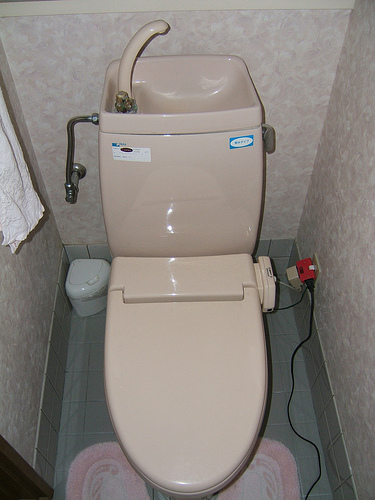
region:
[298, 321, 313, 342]
the chords is black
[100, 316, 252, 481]
the toilet seat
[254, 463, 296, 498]
a pink and white rug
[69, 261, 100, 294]
a white trash can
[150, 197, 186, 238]
a reflection on the toilet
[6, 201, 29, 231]
white cloths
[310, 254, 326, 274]
a wall outlet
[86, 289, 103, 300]
a plastic bag in the trash can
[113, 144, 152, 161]
a sticker on the toilet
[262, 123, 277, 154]
the handle on the toilet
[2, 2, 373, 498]
Toilet in a bathroom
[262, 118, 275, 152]
Silver flusher on a toilet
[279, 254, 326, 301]
Multiple plugs in one outlet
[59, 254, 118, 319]
Small trashcan for personal hygiene objects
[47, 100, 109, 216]
Water supply for toilet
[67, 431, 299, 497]
Pink carpet surrounding toilet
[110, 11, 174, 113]
Faucet behind the toilet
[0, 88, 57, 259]
White linen hanging beside the toilet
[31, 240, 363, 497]
Blue tile on the bathroom floor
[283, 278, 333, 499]
Black cord trailing from bathroom outlet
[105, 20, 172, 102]
the faucet on the toilet tank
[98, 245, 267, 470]
the toilet seat is down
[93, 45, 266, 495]
the toilet in the bathroom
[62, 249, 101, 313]
the waste bin in the corner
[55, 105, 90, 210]
the plumbing in the wall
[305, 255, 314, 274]
the electric outlet on the wall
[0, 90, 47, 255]
the towel is hanging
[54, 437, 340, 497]
the rug on the floor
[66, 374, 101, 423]
the floor is tiled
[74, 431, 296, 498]
the rug is pink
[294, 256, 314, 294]
The reed box has a black plug in it.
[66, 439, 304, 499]
The toilet has a pink carpet by it.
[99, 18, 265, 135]
A drinking fountain is on the toilet top.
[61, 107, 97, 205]
A silver water line is coming out of the wall.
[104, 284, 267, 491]
The toilet lid is white and down.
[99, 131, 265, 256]
The toilet tank has two stickers.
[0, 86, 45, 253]
A white towel is hanging on the wall.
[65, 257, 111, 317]
A white container has a lid on top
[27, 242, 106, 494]
Tile is on the floor and part of the wall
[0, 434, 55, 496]
The metal door frame is brown.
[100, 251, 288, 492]
a white toliet in a bathroom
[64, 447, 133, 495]
a pink and white rug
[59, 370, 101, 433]
tiles on the floor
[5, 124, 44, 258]
a towel hanging on the wall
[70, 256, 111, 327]
a white scrub brush holder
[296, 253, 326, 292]
a red plug plugged in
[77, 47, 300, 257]
tank on the toliet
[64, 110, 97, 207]
water pip in the wall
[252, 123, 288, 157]
a small metal handle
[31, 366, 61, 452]
tiles on the wall